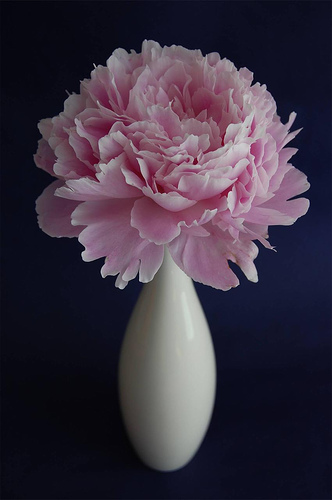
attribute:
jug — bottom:
[126, 354, 216, 471]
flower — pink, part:
[30, 37, 313, 293]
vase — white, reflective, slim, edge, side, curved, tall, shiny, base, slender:
[116, 241, 217, 475]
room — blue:
[1, 2, 330, 499]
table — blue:
[0, 365, 331, 499]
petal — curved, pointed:
[129, 194, 218, 247]